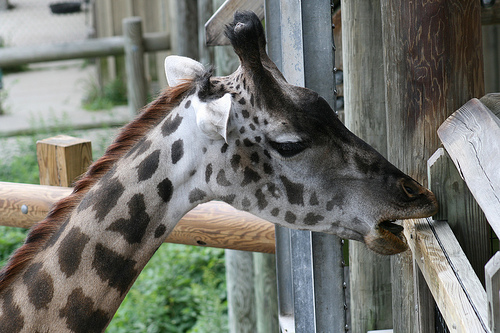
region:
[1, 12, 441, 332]
the giraffe has a mouth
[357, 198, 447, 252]
the giraffe's mouth is open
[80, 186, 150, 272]
the spots are brown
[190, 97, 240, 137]
the ear is white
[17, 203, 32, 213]
the rivet is silver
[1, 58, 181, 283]
the hair is brown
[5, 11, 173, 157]
the fence is behind the grass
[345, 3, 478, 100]
the wood is brown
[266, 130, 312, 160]
the eye is dark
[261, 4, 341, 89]
the metal is grey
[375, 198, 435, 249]
The mouth of the giraffe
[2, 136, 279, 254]
A wooden fence near the giraffe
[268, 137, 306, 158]
The right eye of the giraffe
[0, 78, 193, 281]
The man of the giraffe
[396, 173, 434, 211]
The nose of the giarffe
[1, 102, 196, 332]
The giraffe has a long neck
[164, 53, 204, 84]
The left ear of the giraffe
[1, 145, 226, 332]
Grass beneath the giraffe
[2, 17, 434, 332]
A giraffe near the wooden fence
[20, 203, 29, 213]
A silver nail connected to the fence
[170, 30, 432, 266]
the head of a giraffe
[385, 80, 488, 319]
a wooden fence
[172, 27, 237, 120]
the ear of a giraffe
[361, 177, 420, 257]
the mouth of a giraffe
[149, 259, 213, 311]
bushes behind a fence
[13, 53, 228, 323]
the neck of a giraffe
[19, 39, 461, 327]
a giraffe standing next to a pole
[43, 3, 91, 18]
a tire on the ground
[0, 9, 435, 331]
baby geraffe with mouth on fence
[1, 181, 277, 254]
brown wood fence in back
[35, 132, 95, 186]
square wood behind brown wood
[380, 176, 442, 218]
geraffe nose next to fence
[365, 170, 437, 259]
geraffe mouth next to fence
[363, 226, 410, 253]
geraffe bottom lip almost touching fence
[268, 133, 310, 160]
geraffe eye almost closed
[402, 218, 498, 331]
part of wooden fence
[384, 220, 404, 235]
geraffe tongue toching wooden fence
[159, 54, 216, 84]
geraffe ear behind his head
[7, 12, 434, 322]
giraffe with an open mouth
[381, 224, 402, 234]
the giraffe's black tongue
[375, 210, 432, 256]
the giraffe's mouth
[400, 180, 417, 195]
the giraffe's nostril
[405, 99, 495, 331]
wooden fence in front of the giraffe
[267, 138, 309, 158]
the giraffe's right eye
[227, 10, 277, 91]
horns on the giraffe's head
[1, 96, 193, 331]
the giraffe's neck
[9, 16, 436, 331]
the giraffe about to bite a railing